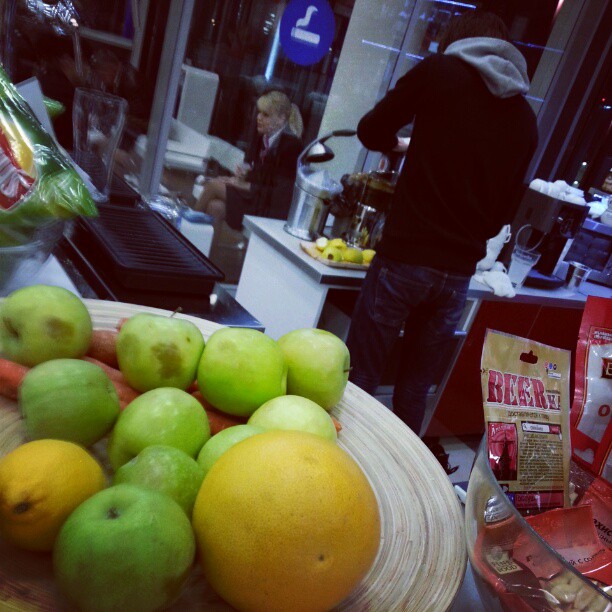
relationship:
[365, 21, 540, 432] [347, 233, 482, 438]
man in jeans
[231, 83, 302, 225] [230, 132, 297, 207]
woman in suit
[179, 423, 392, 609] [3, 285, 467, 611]
grapefruit on dish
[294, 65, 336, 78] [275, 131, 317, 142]
sign with white no smoking insignia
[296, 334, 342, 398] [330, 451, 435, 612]
apple sitting on a plate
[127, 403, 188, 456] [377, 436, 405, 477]
apple sitting on a plate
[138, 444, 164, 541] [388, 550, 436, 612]
apple sitting on a plate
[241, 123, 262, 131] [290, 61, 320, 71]
round blue and white smoking sign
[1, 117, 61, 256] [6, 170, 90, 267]
blurry bags of chips in clear bowl